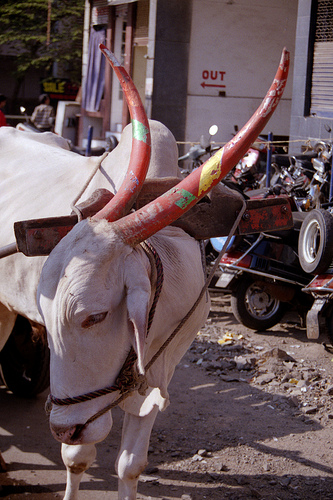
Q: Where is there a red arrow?
A: Under out sign.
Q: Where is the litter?
A: On the ground.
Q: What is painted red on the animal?
A: Horns.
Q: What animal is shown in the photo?
A: A cow.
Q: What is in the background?
A: A building.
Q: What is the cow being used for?
A: Pulling a cart.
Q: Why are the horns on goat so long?
A: They are fake.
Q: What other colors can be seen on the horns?
A: Green and yellow.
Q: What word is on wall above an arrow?
A: Out.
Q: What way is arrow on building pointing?
A: To left.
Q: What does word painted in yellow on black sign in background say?
A: Sale.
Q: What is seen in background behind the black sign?
A: Tree.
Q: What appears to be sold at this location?
A: Used vehicle parts.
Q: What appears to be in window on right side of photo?
A: Blinds.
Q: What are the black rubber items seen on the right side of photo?
A: Tires.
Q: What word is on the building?
A: Out.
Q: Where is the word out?
A: On the building.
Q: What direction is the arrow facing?
A: Left.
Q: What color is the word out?
A: Red.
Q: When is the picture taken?
A: Daytime.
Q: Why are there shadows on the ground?
A: The sun is in the sky.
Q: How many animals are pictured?
A: 1.